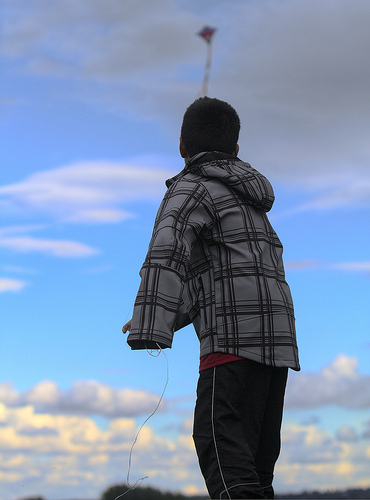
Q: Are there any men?
A: No, there are no men.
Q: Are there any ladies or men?
A: No, there are no men or ladies.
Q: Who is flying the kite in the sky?
A: The boy is flying the kite.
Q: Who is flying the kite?
A: The boy is flying the kite.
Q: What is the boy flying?
A: The boy is flying the kite.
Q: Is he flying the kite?
A: Yes, the boy is flying the kite.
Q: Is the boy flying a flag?
A: No, the boy is flying the kite.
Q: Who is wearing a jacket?
A: The boy is wearing a jacket.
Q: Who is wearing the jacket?
A: The boy is wearing a jacket.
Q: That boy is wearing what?
A: The boy is wearing a jacket.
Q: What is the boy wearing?
A: The boy is wearing a jacket.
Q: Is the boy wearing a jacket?
A: Yes, the boy is wearing a jacket.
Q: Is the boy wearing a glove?
A: No, the boy is wearing a jacket.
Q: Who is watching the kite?
A: The boy is watching the kite.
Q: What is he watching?
A: The boy is watching the kite.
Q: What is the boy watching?
A: The boy is watching the kite.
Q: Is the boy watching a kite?
A: Yes, the boy is watching a kite.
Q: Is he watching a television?
A: No, the boy is watching a kite.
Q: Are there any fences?
A: No, there are no fences.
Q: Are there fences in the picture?
A: No, there are no fences.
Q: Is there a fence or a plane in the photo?
A: No, there are no fences or airplanes.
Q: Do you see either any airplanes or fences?
A: No, there are no fences or airplanes.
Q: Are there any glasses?
A: No, there are no glasses.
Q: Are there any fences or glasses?
A: No, there are no glasses or fences.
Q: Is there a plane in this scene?
A: No, there are no airplanes.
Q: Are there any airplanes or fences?
A: No, there are no airplanes or fences.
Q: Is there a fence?
A: No, there are no fences.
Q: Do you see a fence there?
A: No, there are no fences.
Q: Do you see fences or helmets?
A: No, there are no fences or helmets.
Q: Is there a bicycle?
A: No, there are no bicycles.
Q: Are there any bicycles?
A: No, there are no bicycles.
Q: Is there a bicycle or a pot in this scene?
A: No, there are no bicycles or pots.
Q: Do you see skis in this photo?
A: No, there are no skis.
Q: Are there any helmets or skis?
A: No, there are no skis or helmets.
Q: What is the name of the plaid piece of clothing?
A: The clothing item is a jacket.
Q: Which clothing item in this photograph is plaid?
A: The clothing item is a jacket.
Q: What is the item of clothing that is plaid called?
A: The clothing item is a jacket.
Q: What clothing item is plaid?
A: The clothing item is a jacket.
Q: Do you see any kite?
A: Yes, there is a kite.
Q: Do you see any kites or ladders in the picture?
A: Yes, there is a kite.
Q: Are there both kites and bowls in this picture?
A: No, there is a kite but no bowls.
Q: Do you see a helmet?
A: No, there are no helmets.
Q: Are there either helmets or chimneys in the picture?
A: No, there are no helmets or chimneys.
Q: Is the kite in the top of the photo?
A: Yes, the kite is in the top of the image.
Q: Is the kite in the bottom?
A: No, the kite is in the top of the image.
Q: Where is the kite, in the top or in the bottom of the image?
A: The kite is in the top of the image.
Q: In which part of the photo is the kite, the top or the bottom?
A: The kite is in the top of the image.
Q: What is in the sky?
A: The kite is in the sky.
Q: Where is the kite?
A: The kite is in the sky.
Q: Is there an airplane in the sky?
A: No, there is a kite in the sky.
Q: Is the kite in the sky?
A: Yes, the kite is in the sky.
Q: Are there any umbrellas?
A: No, there are no umbrellas.